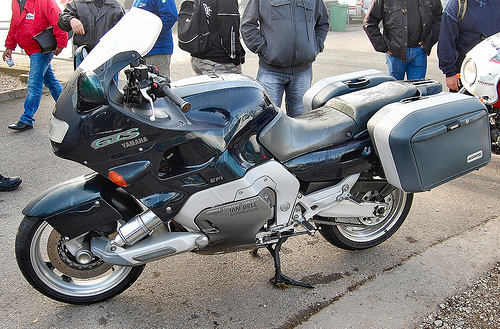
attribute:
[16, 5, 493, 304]
motorcycle — silver, black, gray, honda, yamaha, sided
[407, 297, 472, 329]
rocks — small, gray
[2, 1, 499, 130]
people — standing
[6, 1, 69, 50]
jacket — red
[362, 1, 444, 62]
jacket — black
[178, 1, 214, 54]
backpack — black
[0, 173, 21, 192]
shoe — black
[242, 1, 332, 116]
person — standing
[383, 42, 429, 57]
hands — pocketed